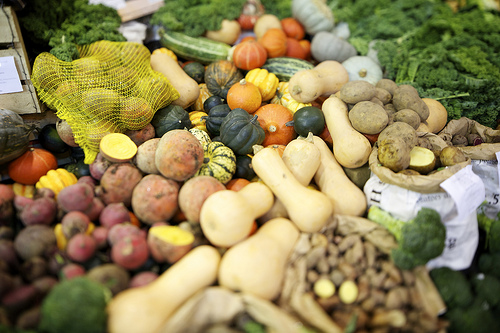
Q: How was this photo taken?
A: By camera.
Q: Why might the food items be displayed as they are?
A: For photo.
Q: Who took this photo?
A: Photographer.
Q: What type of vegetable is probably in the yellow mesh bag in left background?
A: Potatoes.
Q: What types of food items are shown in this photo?
A: Vegetables.